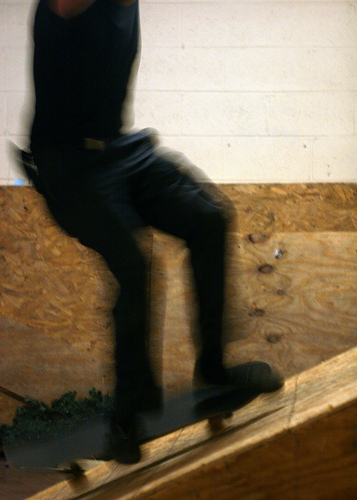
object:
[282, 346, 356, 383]
edge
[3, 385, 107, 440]
grass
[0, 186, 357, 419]
wood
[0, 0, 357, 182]
wall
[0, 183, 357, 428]
wall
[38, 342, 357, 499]
ramp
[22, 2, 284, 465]
man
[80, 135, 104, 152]
buckle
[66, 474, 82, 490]
wheel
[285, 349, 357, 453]
sloppy area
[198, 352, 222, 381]
sock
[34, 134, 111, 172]
trouser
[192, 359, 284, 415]
shoe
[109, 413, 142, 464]
shoe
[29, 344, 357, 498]
bench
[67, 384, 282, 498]
shadow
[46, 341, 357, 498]
board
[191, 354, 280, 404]
sneakers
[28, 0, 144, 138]
shirt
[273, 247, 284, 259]
knots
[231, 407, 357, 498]
wood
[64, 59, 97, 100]
black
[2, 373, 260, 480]
skateboard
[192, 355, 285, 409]
feet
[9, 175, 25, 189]
sticker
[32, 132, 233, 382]
jeans